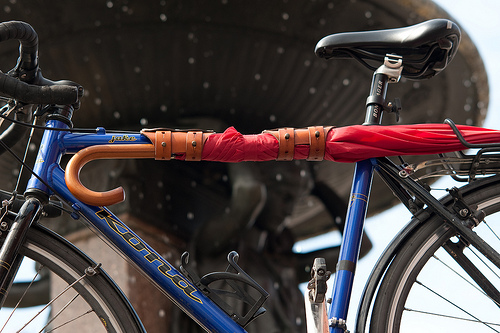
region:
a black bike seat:
[303, 18, 477, 87]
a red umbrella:
[50, 125, 499, 204]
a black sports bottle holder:
[160, 235, 277, 327]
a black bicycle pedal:
[301, 254, 336, 315]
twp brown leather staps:
[140, 121, 212, 170]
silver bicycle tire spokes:
[383, 255, 499, 329]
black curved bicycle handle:
[0, 15, 105, 118]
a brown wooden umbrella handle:
[50, 132, 160, 206]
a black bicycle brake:
[431, 179, 490, 253]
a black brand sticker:
[84, 201, 204, 310]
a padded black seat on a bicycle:
[313, 17, 461, 80]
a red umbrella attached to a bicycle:
[64, 121, 498, 204]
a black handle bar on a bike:
[0, 23, 81, 105]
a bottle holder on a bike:
[175, 237, 270, 330]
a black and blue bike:
[0, 17, 499, 330]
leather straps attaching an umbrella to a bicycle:
[149, 124, 207, 162]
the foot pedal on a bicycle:
[302, 253, 335, 302]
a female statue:
[168, 115, 371, 331]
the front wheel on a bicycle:
[1, 210, 140, 331]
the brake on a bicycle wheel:
[449, 192, 482, 222]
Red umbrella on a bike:
[111, 108, 468, 243]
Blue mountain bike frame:
[41, 118, 198, 273]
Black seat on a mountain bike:
[318, 15, 475, 92]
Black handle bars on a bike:
[6, 38, 83, 143]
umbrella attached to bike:
[133, 110, 420, 210]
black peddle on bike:
[287, 238, 342, 306]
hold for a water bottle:
[169, 240, 277, 320]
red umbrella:
[116, 115, 426, 184]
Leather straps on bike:
[107, 110, 347, 162]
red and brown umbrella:
[64, 120, 499, 205]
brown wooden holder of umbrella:
[65, 135, 161, 201]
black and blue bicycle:
[0, 11, 497, 327]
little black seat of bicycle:
[307, 17, 457, 81]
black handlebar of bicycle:
[0, 15, 65, 150]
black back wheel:
[359, 169, 496, 329]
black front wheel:
[4, 202, 154, 329]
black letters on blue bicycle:
[92, 203, 200, 300]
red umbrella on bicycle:
[150, 126, 498, 160]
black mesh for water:
[175, 247, 265, 332]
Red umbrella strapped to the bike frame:
[51, 115, 498, 207]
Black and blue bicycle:
[1, 9, 499, 330]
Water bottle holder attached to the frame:
[168, 240, 279, 325]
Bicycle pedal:
[305, 253, 330, 305]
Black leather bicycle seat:
[311, 16, 468, 83]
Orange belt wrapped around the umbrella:
[139, 122, 335, 172]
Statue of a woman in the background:
[0, 0, 496, 332]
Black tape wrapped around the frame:
[333, 253, 364, 280]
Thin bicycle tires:
[348, 175, 499, 332]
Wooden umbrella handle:
[60, 137, 165, 209]